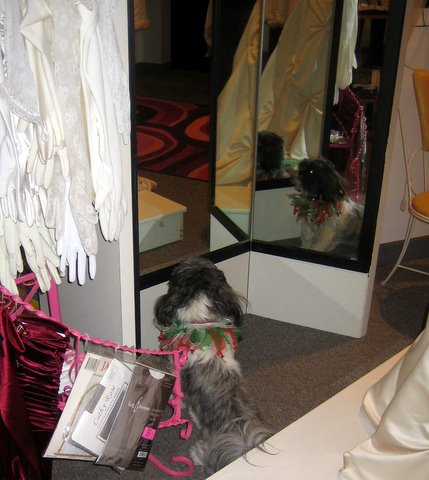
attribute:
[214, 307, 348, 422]
floor — grey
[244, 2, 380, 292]
mirror — glass, tall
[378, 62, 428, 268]
seat — brown, chair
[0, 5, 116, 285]
clothes — white, hanging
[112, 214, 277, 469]
pet — black, reflected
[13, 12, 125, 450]
wardrobe — open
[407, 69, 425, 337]
chair — yellow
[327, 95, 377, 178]
reflection — brown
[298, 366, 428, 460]
sheet — white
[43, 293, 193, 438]
leash — pink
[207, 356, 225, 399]
fur — grey, long, white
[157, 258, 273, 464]
dog — pet, sitting, white, grey